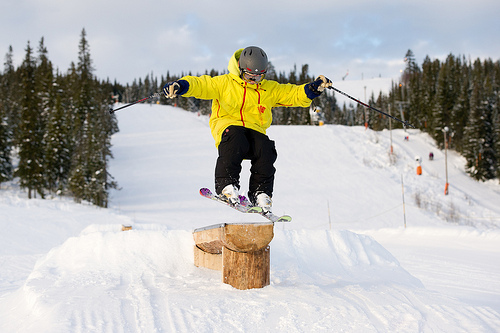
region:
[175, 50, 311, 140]
yellow coat on skiier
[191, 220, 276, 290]
log bench under skiier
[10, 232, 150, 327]
snow hill for skiiers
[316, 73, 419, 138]
ski pole in left hand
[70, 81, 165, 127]
ski pole on right hand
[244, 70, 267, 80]
goggles on skiier's face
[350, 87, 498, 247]
ski lift background right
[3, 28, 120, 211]
pine trees in background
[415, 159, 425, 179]
orange safety object on ski lift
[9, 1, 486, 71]
partly cloudy sky in background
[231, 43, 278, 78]
beige ski helmet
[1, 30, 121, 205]
row of tall evergreen trees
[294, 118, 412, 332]
steep snow covered hills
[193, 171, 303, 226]
pair of skiis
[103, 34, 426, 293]
man jumping over tree stumps while skiiing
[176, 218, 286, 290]
cut wood tree stumps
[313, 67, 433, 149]
black ski pole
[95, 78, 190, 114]
black and yellow gloved hand holding ski pole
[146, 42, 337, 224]
person skiing wearing yellow and black snowsuit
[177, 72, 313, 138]
yellow jacket with red accents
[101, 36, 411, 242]
A man skiing down a large slope.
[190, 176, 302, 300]
A man doing a jump trick while skiing.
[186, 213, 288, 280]
An object for skiers to jump from.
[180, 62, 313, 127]
A bright yellow coat.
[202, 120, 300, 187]
Warm black pants for winter sports.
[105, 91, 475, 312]
A large hill for skiing.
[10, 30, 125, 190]
Trees all around in the top of the hill.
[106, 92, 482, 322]
Snow covering all the terrain.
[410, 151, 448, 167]
Another skier in the distance.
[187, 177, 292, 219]
Skis on his feet.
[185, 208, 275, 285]
Small bench made of wood.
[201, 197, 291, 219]
The skis are in the air.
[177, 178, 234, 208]
Purple on the skis.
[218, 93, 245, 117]
The jacket is yellow.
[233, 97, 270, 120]
Red line on the jacket.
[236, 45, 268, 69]
Person is wearing a helmet.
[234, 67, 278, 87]
Person is wearing goggles.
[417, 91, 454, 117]
The trees are green.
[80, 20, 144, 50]
The sky is grey.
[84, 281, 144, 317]
Snow on the ground.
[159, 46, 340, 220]
Skier wearing a yellow ski outfit.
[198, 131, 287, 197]
Black pants being worn by a person skiing.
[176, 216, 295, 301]
Obstacle in the middle of white snow.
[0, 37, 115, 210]
Forest lining a snow covered slope.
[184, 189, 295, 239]
Skis being worn by a skier.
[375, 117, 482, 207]
Ski lift off in the distance.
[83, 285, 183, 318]
Tracks left in the snow by skis.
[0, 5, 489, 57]
cloud filled blue sky.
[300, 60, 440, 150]
A hand holding a ski pole.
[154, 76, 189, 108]
The right hand of a man skiing.